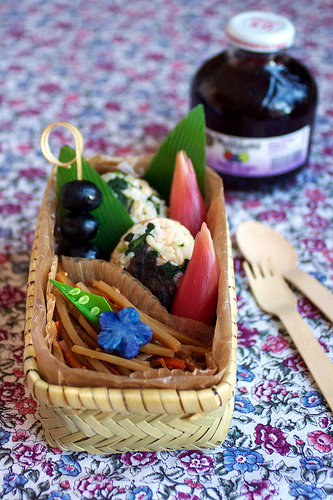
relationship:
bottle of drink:
[184, 10, 322, 186] [192, 51, 316, 181]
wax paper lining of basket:
[47, 149, 213, 382] [20, 143, 241, 457]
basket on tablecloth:
[20, 143, 241, 457] [1, 2, 331, 496]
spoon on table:
[234, 219, 331, 320] [0, 0, 331, 498]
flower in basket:
[94, 302, 152, 360] [20, 143, 241, 457]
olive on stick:
[58, 179, 104, 212] [39, 119, 84, 178]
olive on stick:
[54, 209, 101, 243] [39, 119, 84, 178]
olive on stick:
[53, 241, 101, 260] [39, 119, 84, 178]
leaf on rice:
[173, 105, 207, 149] [162, 230, 188, 250]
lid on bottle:
[225, 10, 295, 53] [190, 9, 318, 193]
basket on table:
[22, 143, 240, 457] [33, 36, 153, 114]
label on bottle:
[204, 125, 311, 176] [190, 9, 318, 193]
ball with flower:
[102, 165, 170, 219] [122, 177, 158, 220]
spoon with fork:
[237, 219, 333, 323] [236, 268, 308, 336]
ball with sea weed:
[109, 216, 200, 310] [113, 216, 200, 309]